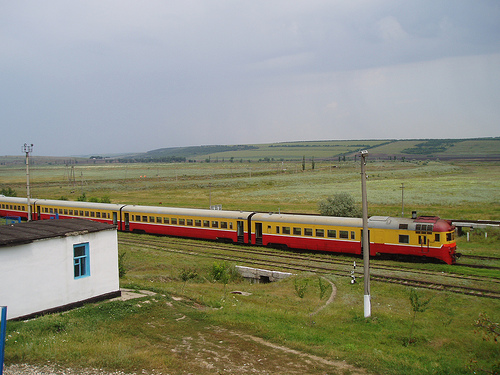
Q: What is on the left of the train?
A: A building.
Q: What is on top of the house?
A: A roof.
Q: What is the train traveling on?
A: Tracks.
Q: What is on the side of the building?
A: A window.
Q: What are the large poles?
A: Light poles.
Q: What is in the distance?
A: Hills.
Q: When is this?
A: Daytime.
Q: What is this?
A: Train.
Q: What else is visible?
A: Tracks.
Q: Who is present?
A: No one.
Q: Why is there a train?
A: Travelling.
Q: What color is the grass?
A: Green.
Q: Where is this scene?
A: At the train tracks.